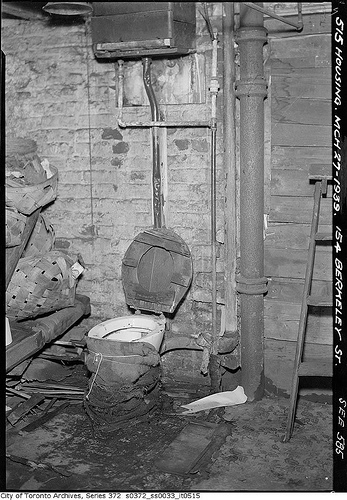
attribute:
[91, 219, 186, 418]
toilet — broken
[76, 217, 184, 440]
toilet — broken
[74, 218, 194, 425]
toilet — broken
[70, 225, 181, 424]
toilet — broken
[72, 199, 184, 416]
toilet — broken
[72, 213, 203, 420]
toilet — broken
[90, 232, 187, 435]
toilet — broken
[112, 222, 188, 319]
lid — broken, toilet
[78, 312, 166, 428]
toilet — base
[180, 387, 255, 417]
paper — white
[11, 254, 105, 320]
basket — weaved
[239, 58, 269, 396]
pipe — metal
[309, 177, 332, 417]
ladder — wooden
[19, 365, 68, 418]
wood — pile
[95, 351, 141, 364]
cord — piece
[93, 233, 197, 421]
toilet — broken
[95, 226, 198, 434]
toilet — bottom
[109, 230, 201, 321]
seat — wooden, toilet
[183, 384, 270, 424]
trash — piece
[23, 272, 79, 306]
basket — wooden, broken, stack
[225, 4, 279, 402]
pipe — long, thick, dark colored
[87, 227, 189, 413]
toilet — broken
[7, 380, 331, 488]
ground — dirty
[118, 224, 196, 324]
toilet seat — wooden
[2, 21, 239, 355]
wall — brick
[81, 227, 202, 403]
toilet — broken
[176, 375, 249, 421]
paper — white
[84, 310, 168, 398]
toilet bowl — white